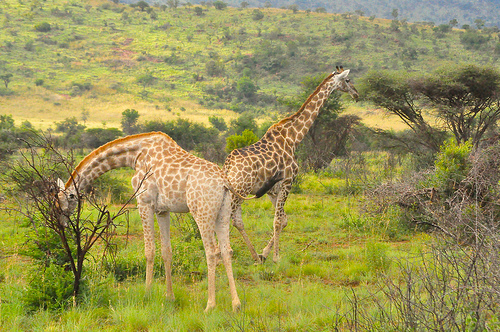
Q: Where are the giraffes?
A: In the field.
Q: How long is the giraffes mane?
A: From top of head down to shoulders.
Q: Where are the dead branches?
A: Foreground.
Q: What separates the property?
A: Dirt road.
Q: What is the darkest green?
A: Bushes.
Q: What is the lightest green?
A: Grass.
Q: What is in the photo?
A: Giraffes.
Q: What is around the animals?
A: Trees.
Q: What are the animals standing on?
A: Grass.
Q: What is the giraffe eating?
A: Tree.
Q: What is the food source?
A: Trees.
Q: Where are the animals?
A: In the plains.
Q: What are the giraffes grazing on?
A: Leaves.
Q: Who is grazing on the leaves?
A: Giraffes.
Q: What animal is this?
A: Giraffe.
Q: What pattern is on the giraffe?
A: Brown spots.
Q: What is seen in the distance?
A: Hills.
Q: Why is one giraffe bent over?
A: To graze on tree.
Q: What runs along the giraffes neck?
A: Light brown hair.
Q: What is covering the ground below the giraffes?
A: Bright green grass.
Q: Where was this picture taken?
A: In the wild.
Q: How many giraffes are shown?
A: Two.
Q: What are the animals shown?
A: Giraffes.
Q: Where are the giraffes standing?
A: Plains.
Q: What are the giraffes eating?
A: Leaves.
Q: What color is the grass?
A: Green.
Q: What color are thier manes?
A: Brown.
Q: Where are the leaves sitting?
A: Trees.